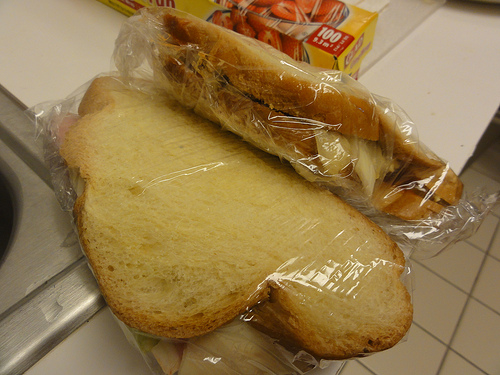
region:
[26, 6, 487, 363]
sandwich wrapped in plastic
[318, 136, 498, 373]
a beige tile floor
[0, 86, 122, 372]
a stainless steel sink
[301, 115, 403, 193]
meat hanging out of the sandwich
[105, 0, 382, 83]
a box of plastic wrap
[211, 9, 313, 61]
a picture of strawberries on the box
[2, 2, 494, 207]
a beige counter top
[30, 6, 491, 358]
the sandwiches are wrapped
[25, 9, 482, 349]
sandwiches on the counter top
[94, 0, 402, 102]
sandwiches beside a box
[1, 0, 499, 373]
A photo of food in a food prep area.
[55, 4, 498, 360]
Two sandwiches in plastic wrap.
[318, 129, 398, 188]
A small view of cheese.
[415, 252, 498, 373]
The tan tile on the counter top.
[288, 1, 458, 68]
A box of plastic wrap.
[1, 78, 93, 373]
The stainless steel sink.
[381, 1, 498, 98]
A white cutting board.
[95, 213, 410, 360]
A yellow colored slice of bread.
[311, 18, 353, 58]
The length of the plastic wrap.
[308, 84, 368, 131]
The crust of the bread.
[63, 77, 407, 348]
slice of potatoe bread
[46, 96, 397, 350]
sandwich in plastic bag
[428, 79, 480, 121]
white table top counter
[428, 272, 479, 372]
white tile with brown grout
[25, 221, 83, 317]
silver portion of stove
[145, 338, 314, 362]
brown paper napkin in bag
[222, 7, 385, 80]
box of plastic Ziploc bags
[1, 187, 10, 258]
coils for stovetop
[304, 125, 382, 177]
piece of turkey for sandwhich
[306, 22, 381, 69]
100 quantity labeled box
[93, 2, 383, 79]
Box of Plastic Wrap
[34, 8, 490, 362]
Plastic Wrap Really Clings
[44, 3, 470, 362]
Sandwich is made with white bread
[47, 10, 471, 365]
Sandwich is not made with Beef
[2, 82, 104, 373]
Part of the Sink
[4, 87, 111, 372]
Sink is Stainless Steel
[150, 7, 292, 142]
There is a messy sauce on the sandwich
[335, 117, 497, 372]
The Kitchen floor is made of tile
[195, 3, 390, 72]
The Photo on the box shows Strawberries wrapped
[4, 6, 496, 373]
Two wrapped Sandwiches on the kitchen counter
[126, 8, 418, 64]
yellow box of plastic wrap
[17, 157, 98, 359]
silver sink with a water drop on it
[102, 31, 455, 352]
two sandwhiches in plastic wrap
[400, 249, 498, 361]
white square tile on floor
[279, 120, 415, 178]
light green lettuce in sandwich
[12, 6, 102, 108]
white kitchen counter top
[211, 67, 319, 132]
brown crust on bread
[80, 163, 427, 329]
bread with a tint of yellow and brown crust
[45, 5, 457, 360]
sandwiches on kitchen counter